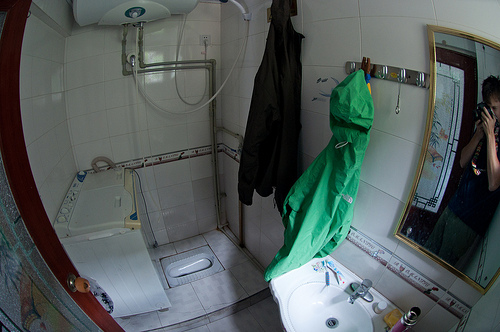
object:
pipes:
[137, 23, 229, 228]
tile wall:
[64, 0, 221, 244]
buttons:
[54, 214, 72, 224]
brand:
[345, 195, 353, 205]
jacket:
[263, 67, 375, 283]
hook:
[361, 56, 372, 82]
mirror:
[391, 24, 499, 296]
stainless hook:
[410, 68, 422, 87]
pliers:
[360, 55, 372, 74]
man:
[425, 74, 500, 274]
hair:
[480, 76, 499, 100]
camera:
[469, 98, 498, 123]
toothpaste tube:
[324, 260, 348, 288]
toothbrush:
[320, 261, 330, 288]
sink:
[288, 281, 373, 332]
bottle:
[388, 306, 422, 332]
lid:
[407, 307, 419, 320]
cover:
[74, 277, 91, 297]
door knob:
[66, 272, 92, 294]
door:
[2, 1, 126, 331]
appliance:
[53, 167, 173, 318]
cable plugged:
[133, 0, 249, 115]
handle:
[362, 73, 373, 99]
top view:
[269, 248, 413, 332]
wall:
[222, 0, 500, 330]